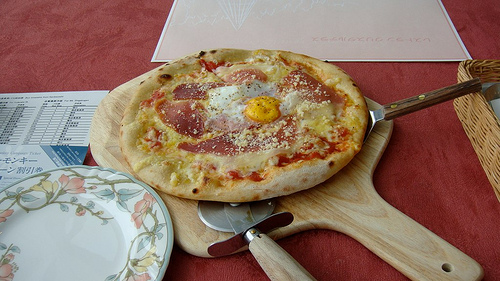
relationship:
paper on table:
[1, 93, 95, 189] [2, 2, 496, 278]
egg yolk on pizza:
[246, 93, 278, 124] [120, 49, 369, 203]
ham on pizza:
[164, 99, 218, 132] [120, 49, 369, 203]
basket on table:
[452, 66, 500, 162] [2, 2, 496, 278]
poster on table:
[157, 4, 473, 62] [2, 2, 496, 278]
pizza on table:
[120, 49, 369, 203] [2, 2, 496, 278]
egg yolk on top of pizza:
[246, 93, 278, 124] [120, 49, 369, 203]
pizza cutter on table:
[196, 196, 314, 277] [2, 2, 496, 278]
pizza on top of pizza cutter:
[120, 49, 369, 203] [196, 196, 314, 277]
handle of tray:
[336, 194, 489, 279] [96, 72, 494, 280]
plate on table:
[6, 166, 173, 279] [2, 2, 496, 278]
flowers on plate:
[32, 174, 91, 205] [6, 166, 173, 279]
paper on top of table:
[1, 93, 95, 189] [2, 2, 496, 278]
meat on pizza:
[282, 74, 337, 110] [120, 49, 369, 203]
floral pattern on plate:
[119, 192, 179, 270] [6, 166, 173, 279]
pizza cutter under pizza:
[196, 196, 314, 277] [120, 49, 369, 203]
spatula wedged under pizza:
[355, 71, 485, 145] [120, 49, 369, 203]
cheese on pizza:
[233, 122, 281, 141] [120, 49, 369, 203]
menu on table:
[1, 93, 95, 189] [2, 2, 496, 278]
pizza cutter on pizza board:
[196, 196, 314, 277] [2, 2, 496, 278]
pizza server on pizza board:
[355, 71, 485, 145] [96, 72, 494, 280]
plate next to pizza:
[6, 166, 173, 279] [120, 49, 369, 203]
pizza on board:
[120, 49, 369, 203] [96, 72, 494, 280]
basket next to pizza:
[452, 66, 500, 162] [120, 49, 369, 203]